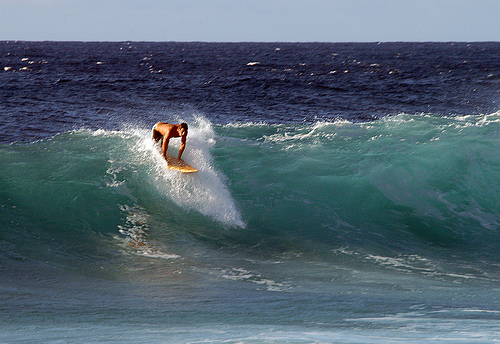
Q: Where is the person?
A: Ocean.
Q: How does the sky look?
A: Clear.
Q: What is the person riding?
A: Surfboard.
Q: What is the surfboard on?
A: Wave.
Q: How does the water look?
A: Clear blue.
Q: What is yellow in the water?
A: Surfboard.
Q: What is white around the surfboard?
A: Foam.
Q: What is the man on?
A: A surfboard.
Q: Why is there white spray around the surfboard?
A: The surfboard is breaking up the wave.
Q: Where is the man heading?
A: Towards the shore.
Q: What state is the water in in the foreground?
A: Calm.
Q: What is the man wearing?
A: Swimming trunks.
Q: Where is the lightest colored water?
A: At the crest of the wave.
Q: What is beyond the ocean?
A: The sky.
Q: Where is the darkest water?
A: At the horizon.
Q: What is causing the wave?
A: The tide.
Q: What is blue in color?
A: The ocean.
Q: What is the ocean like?
A: Calm.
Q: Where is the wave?
A: In the ocean.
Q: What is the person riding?
A: A surfboard.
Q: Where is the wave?
A: Under the surfer.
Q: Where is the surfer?
A: In the ocean.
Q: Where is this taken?
A: At the beach.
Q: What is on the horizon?
A: Calm water.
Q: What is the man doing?
A: Surfing.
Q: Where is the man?
A: On a surfboard.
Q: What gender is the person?
A: Male.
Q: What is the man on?
A: Surfboard.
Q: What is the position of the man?
A: Bent over.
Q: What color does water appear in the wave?
A: Green.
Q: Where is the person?
A: In the water.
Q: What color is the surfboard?
A: Yellow.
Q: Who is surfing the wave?
A: Person.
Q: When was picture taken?
A: Daytime.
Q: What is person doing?
A: Surfing.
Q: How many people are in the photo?
A: One.